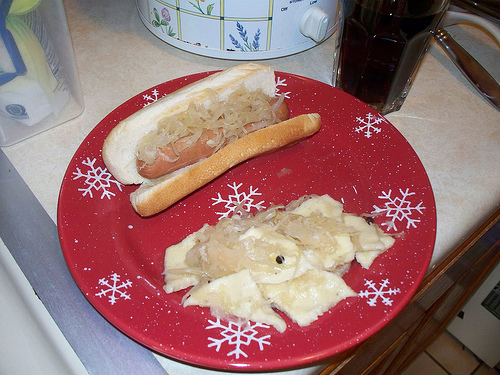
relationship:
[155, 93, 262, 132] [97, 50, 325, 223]
sauerkraut on hot dog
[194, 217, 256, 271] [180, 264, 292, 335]
sauerkraut on ravioli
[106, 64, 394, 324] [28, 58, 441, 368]
dinner on plate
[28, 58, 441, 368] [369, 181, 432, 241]
plate has snowflakes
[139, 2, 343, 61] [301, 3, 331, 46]
crock pot has dial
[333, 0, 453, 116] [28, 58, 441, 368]
bottom next to plate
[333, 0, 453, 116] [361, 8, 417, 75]
bottom of soda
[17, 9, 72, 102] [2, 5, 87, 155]
silverware in canister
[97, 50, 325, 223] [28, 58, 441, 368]
hot dog on plate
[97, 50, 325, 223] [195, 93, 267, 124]
hot dog has cheese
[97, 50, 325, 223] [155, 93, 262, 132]
hot dog has sauerkraut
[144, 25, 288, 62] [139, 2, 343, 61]
bottom of crock pot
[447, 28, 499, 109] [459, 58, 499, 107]
knife has handle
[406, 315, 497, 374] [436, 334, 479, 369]
floor has tile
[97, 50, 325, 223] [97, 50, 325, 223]
hot dog on hot dog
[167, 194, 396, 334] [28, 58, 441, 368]
pasta on plate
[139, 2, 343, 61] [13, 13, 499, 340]
crock pot on table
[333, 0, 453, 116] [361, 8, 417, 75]
bottom has soda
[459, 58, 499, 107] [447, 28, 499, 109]
handle of knife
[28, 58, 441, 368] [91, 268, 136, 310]
plate has snowflakes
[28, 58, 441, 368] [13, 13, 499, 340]
plate on table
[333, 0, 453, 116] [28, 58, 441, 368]
bottom near plate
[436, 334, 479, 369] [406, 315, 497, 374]
tile on floor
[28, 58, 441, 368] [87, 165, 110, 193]
plate has stars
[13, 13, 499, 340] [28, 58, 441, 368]
table under plate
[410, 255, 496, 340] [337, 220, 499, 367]
front of cabinet